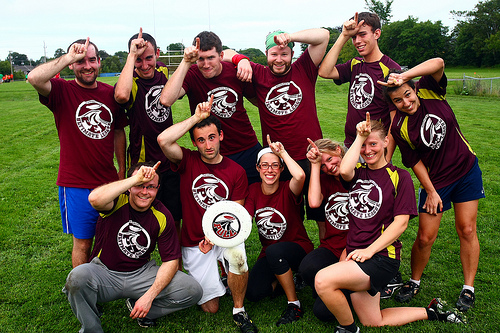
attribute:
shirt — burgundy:
[244, 60, 318, 143]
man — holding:
[160, 95, 257, 326]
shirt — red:
[37, 73, 132, 187]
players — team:
[21, 17, 498, 327]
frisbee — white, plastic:
[202, 200, 251, 248]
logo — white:
[173, 154, 237, 218]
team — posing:
[27, 11, 484, 331]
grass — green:
[4, 117, 49, 332]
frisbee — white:
[204, 191, 254, 252]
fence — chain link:
[454, 72, 499, 92]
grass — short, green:
[1, 69, 497, 332]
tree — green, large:
[453, 0, 498, 65]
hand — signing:
[271, 27, 291, 52]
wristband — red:
[231, 45, 253, 59]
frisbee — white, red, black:
[202, 199, 254, 250]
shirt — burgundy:
[390, 71, 475, 188]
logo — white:
[421, 114, 446, 149]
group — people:
[23, 11, 486, 331]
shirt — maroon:
[168, 139, 283, 240]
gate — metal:
[456, 73, 497, 100]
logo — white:
[75, 99, 112, 137]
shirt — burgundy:
[39, 77, 120, 185]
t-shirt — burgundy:
[185, 64, 260, 151]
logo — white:
[205, 86, 240, 121]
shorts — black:
[371, 246, 397, 286]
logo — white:
[75, 101, 113, 146]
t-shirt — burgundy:
[105, 204, 161, 279]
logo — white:
[120, 223, 146, 257]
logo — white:
[265, 77, 305, 117]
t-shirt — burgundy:
[175, 141, 253, 248]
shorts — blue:
[54, 181, 124, 240]